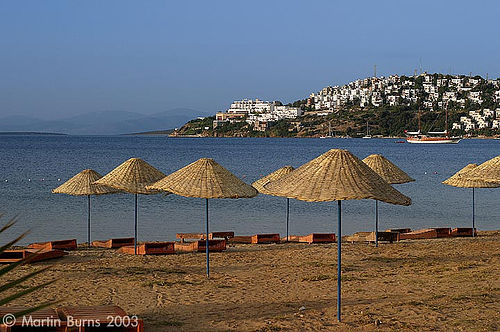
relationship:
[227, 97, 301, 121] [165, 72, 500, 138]
building on island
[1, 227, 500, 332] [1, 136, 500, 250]
sand along ocean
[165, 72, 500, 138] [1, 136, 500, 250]
island in ocean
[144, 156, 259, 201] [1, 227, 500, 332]
sunbrella on beach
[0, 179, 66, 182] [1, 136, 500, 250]
rope in water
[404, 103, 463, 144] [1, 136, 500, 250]
boat on water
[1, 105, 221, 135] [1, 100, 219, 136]
mountains in distance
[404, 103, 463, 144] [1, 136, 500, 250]
ship in water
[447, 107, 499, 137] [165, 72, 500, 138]
buildings in hill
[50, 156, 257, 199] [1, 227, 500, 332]
umbrellas on beach